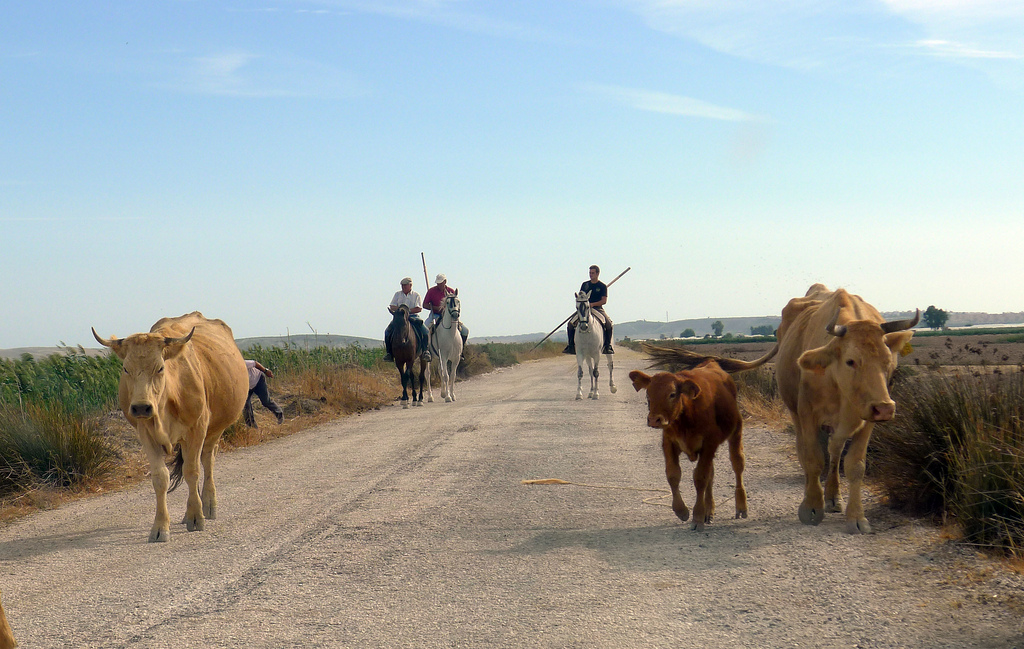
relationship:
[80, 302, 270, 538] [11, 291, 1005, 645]
cow walking on road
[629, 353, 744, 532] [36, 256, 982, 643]
cow walking on road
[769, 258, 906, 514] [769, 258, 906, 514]
cow walking on road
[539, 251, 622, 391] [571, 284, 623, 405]
man riding horse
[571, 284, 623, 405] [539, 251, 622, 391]
horse on road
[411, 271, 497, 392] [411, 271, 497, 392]
man riding horse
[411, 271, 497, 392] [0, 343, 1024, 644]
horse on road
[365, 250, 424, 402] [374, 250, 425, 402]
man riding horse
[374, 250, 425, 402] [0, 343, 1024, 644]
horse on road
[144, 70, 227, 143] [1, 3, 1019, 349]
clouds in sky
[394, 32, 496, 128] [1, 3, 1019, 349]
clouds in sky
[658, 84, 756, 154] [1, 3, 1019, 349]
clouds in sky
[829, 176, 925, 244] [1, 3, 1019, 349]
clouds in sky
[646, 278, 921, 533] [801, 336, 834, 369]
cow has ear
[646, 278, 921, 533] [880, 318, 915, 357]
cow has ear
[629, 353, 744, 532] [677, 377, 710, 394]
cow has ear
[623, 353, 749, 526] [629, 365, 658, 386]
cow has ear